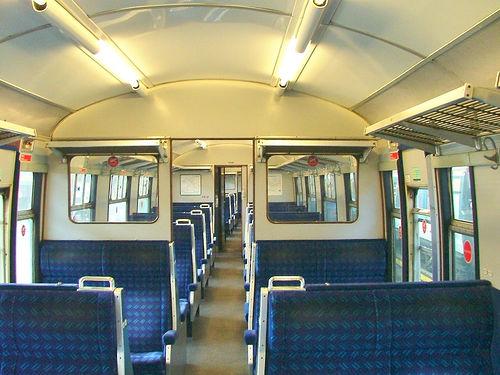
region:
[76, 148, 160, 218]
window of a train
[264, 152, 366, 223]
window of a train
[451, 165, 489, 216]
window of a train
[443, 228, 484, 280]
window of a train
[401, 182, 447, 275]
window of a train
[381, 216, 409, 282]
window of a train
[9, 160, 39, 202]
window of a train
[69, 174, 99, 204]
window of a train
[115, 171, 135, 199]
window of a train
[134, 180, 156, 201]
window of a train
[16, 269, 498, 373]
The first row of chairs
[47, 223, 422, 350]
The second row of chairs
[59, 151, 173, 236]
The window on the left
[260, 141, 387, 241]
The window on the right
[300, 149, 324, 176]
The red sticker on the window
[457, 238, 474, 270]
The red sticker on the window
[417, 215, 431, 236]
The red sticker on the window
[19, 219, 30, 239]
The red sticker on the window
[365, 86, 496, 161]
The shelf above the window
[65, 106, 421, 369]
the inside of a train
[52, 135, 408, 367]
a train with seats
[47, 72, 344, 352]
a train with blue seats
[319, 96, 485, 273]
a train with windows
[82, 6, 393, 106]
a train with lgihts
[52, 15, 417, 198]
light son the ceiling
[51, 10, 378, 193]
lights on the train ceiling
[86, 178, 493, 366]
blue seats on a train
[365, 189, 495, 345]
windows on a train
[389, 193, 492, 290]
red stickers on the window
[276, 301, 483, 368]
the bus seat is blue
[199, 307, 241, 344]
a shadow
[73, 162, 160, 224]
a windshield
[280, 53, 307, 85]
a light in the cealing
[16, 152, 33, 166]
an exit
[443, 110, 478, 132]
a vent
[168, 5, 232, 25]
a reflection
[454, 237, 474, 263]
a sticker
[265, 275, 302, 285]
a handle on the seat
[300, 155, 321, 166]
a red light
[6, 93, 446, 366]
passenger wagon is empty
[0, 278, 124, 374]
bench covered with blue fabric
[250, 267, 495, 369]
bench covered with blue fabric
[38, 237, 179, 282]
bench covered with blue fabric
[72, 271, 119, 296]
handle bar on top of bench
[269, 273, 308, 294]
handle bar on top of bench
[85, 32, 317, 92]
artificial light on ceiling is on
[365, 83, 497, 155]
rack on top of train wall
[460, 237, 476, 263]
red sticker affixed on window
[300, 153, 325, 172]
red sticker affixed on window